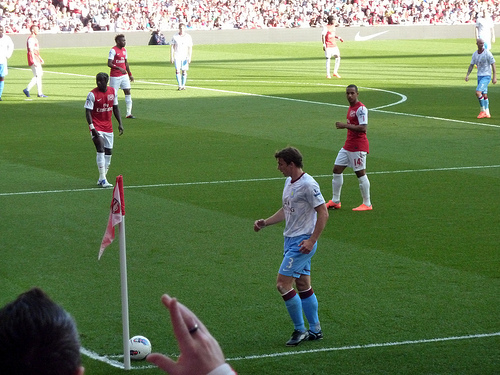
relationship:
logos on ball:
[132, 339, 152, 349] [129, 335, 152, 360]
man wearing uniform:
[463, 36, 500, 123] [474, 57, 487, 93]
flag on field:
[80, 179, 139, 318] [38, 124, 489, 374]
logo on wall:
[351, 28, 402, 52] [265, 25, 486, 47]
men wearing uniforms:
[25, 27, 155, 186] [85, 53, 138, 162]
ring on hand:
[189, 325, 206, 336] [145, 303, 231, 372]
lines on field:
[237, 70, 447, 125] [38, 124, 489, 374]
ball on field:
[129, 335, 152, 360] [38, 124, 489, 374]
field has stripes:
[38, 124, 489, 374] [128, 163, 495, 182]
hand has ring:
[145, 303, 231, 372] [189, 325, 206, 336]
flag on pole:
[80, 179, 139, 318] [117, 241, 132, 369]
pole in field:
[117, 241, 132, 369] [38, 124, 489, 374]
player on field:
[243, 140, 352, 334] [38, 124, 489, 374]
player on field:
[331, 83, 390, 233] [38, 124, 489, 374]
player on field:
[69, 67, 116, 173] [38, 124, 489, 374]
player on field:
[304, 13, 352, 88] [38, 124, 489, 374]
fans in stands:
[233, 1, 430, 28] [34, 5, 409, 51]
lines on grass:
[237, 70, 447, 125] [147, 106, 320, 176]